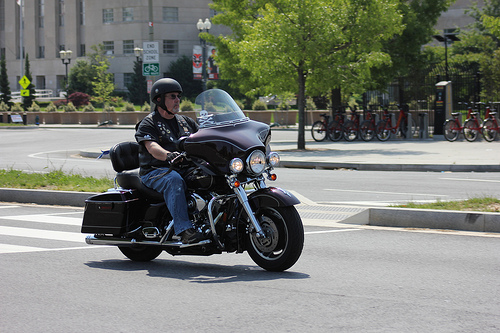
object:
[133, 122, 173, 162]
arm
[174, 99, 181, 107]
nose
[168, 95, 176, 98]
eye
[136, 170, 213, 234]
leg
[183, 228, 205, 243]
foot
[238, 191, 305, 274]
wheel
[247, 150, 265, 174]
light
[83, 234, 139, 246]
muffler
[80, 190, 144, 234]
carrying case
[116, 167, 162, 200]
seat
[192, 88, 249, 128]
windshield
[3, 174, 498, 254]
crosswalk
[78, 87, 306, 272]
motorcycle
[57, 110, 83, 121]
planter container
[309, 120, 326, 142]
bike tire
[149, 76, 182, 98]
helmet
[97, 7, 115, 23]
window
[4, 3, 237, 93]
building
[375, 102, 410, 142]
bicycles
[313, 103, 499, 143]
rack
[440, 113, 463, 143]
bicycles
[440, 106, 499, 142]
rack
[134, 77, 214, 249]
man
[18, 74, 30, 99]
sign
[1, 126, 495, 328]
road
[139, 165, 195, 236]
jeans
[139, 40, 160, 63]
sign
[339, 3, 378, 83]
leaves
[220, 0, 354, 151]
tree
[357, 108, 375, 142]
bikes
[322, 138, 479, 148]
sidewalk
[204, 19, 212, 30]
lights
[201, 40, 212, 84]
pole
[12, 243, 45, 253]
lines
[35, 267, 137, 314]
street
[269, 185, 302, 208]
fender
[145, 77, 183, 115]
head